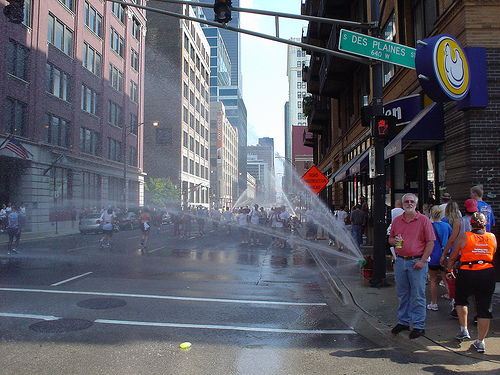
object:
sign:
[297, 165, 330, 198]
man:
[388, 193, 436, 339]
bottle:
[395, 234, 403, 250]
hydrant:
[358, 255, 374, 287]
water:
[0, 18, 366, 282]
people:
[99, 209, 114, 248]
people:
[138, 207, 152, 248]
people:
[6, 206, 21, 255]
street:
[1, 222, 450, 375]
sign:
[338, 28, 417, 70]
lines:
[0, 287, 327, 306]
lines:
[0, 312, 358, 334]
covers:
[29, 317, 94, 333]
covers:
[76, 297, 128, 309]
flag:
[0, 133, 34, 161]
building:
[0, 0, 147, 232]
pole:
[0, 129, 17, 148]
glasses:
[403, 200, 416, 203]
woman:
[447, 211, 498, 352]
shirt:
[459, 229, 494, 271]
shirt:
[390, 210, 437, 256]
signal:
[378, 119, 388, 134]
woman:
[427, 205, 454, 311]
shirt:
[428, 221, 453, 266]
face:
[404, 194, 416, 212]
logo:
[444, 42, 465, 90]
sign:
[415, 33, 472, 102]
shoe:
[409, 328, 425, 339]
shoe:
[391, 323, 409, 334]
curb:
[294, 225, 353, 305]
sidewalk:
[295, 222, 500, 375]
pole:
[367, 32, 391, 286]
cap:
[464, 199, 479, 213]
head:
[464, 199, 478, 215]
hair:
[402, 193, 418, 204]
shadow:
[329, 348, 500, 375]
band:
[462, 260, 494, 268]